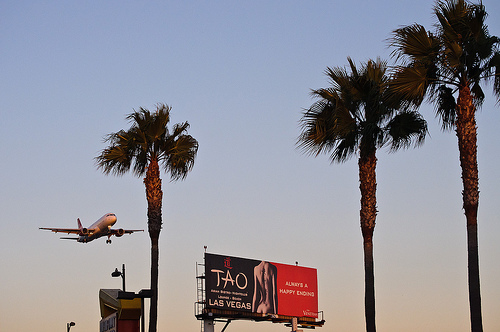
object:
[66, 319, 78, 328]
streetlight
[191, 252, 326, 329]
sign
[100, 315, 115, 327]
sign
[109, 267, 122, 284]
lamp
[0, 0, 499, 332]
sky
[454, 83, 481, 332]
tree trunk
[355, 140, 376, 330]
tree trunk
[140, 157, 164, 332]
tree trunk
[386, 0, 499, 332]
trees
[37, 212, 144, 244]
airplane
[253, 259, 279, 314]
person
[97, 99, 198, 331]
palm tree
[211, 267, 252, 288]
lettering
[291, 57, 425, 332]
palm